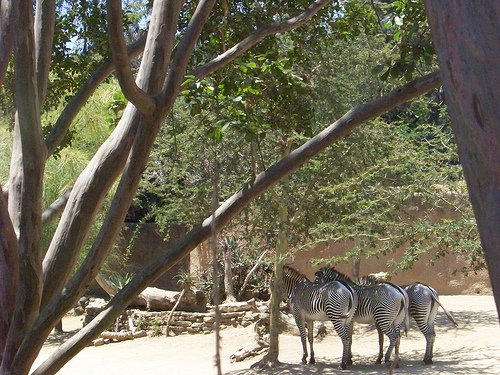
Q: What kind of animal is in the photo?
A: Zebras.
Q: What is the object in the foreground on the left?
A: Tree.